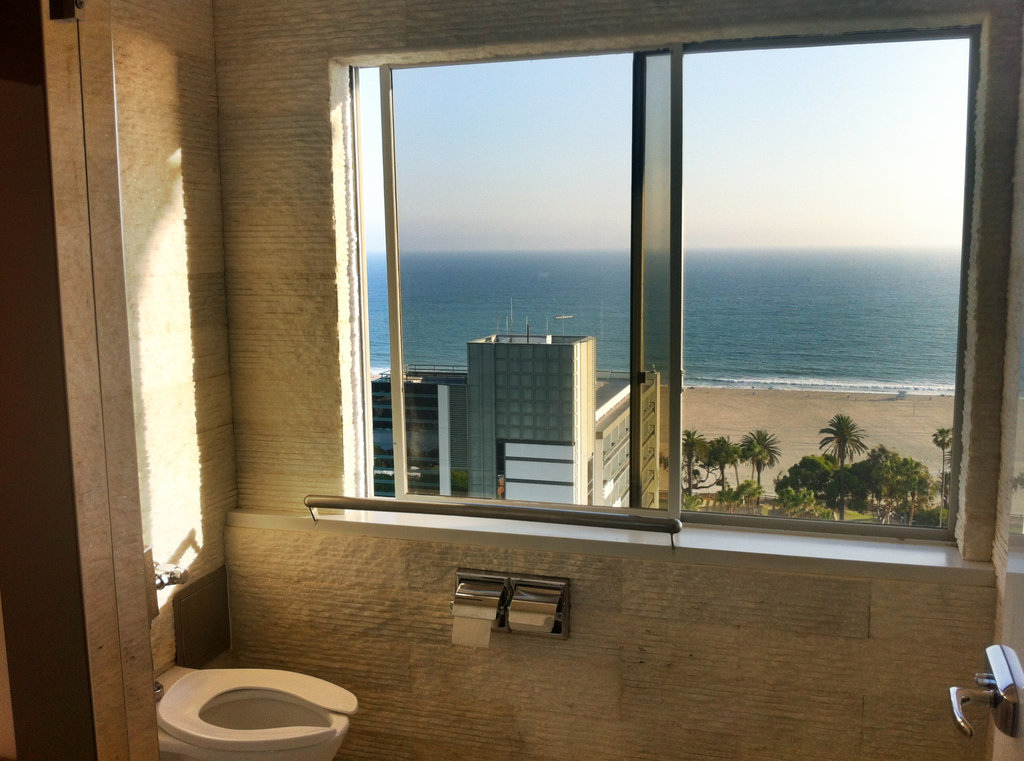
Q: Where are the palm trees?
A: Outside window.